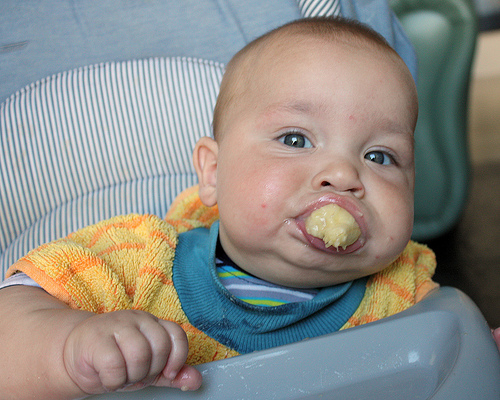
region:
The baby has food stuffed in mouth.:
[283, 191, 363, 252]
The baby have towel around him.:
[67, 218, 449, 370]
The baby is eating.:
[50, 103, 451, 396]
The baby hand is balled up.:
[67, 305, 209, 383]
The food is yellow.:
[296, 206, 347, 251]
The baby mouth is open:
[285, 205, 377, 272]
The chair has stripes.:
[38, 61, 180, 203]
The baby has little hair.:
[244, 30, 387, 52]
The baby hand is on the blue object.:
[53, 296, 484, 383]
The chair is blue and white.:
[9, 10, 208, 130]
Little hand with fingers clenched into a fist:
[67, 302, 203, 397]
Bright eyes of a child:
[269, 123, 419, 168]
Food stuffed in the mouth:
[293, 200, 366, 256]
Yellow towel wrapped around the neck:
[13, 240, 449, 327]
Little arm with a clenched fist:
[0, 278, 205, 398]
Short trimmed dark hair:
[207, 13, 422, 131]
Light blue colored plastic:
[81, 280, 498, 397]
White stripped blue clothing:
[0, 55, 226, 280]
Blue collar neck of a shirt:
[178, 226, 376, 357]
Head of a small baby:
[186, 0, 426, 292]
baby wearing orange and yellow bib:
[5, 183, 440, 367]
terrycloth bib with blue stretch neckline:
[2, 183, 438, 365]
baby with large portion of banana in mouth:
[0, 15, 437, 398]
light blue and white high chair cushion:
[0, 0, 417, 280]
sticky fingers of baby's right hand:
[62, 310, 203, 394]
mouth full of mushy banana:
[293, 193, 370, 255]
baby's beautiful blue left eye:
[365, 143, 399, 166]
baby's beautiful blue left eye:
[267, 125, 314, 150]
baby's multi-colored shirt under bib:
[212, 235, 322, 305]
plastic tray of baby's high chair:
[82, 285, 498, 399]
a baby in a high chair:
[3, 1, 498, 396]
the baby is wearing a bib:
[11, 19, 443, 399]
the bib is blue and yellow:
[8, 185, 440, 365]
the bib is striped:
[8, 179, 444, 369]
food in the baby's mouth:
[287, 197, 368, 254]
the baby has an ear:
[189, 135, 225, 205]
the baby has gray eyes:
[276, 124, 388, 173]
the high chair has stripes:
[1, 55, 223, 281]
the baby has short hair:
[208, 17, 420, 140]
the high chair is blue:
[2, 0, 497, 398]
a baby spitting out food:
[196, 13, 425, 291]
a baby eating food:
[193, 7, 457, 288]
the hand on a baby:
[57, 303, 203, 391]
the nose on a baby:
[317, 155, 362, 190]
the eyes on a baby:
[280, 121, 403, 166]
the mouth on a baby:
[287, 188, 373, 254]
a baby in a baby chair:
[3, 2, 445, 397]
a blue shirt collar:
[157, 220, 363, 343]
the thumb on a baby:
[157, 363, 207, 390]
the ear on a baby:
[186, 138, 226, 206]